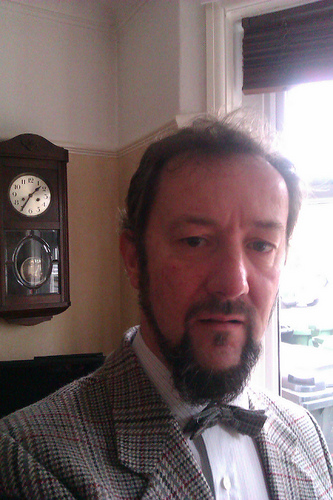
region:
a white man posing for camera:
[0, 105, 332, 497]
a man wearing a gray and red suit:
[0, 106, 330, 496]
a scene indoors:
[1, 0, 331, 498]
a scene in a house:
[4, 0, 328, 495]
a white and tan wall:
[0, 1, 197, 365]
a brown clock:
[0, 121, 84, 348]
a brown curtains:
[235, 0, 331, 106]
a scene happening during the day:
[3, 0, 318, 499]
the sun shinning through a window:
[221, 11, 332, 407]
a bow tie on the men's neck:
[173, 387, 280, 454]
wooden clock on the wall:
[0, 122, 79, 328]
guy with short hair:
[10, 111, 332, 493]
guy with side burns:
[1, 55, 332, 498]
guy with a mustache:
[5, 91, 328, 498]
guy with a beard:
[0, 99, 332, 495]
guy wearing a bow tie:
[0, 115, 329, 498]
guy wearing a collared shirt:
[1, 131, 332, 499]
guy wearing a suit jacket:
[1, 113, 331, 497]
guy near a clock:
[0, 103, 329, 498]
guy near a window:
[0, 62, 330, 496]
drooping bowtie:
[181, 401, 269, 443]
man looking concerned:
[103, 102, 308, 414]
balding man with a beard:
[109, 104, 305, 414]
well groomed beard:
[132, 257, 276, 415]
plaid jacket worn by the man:
[0, 314, 331, 499]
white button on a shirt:
[218, 475, 232, 492]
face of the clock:
[8, 169, 51, 217]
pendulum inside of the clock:
[11, 233, 51, 296]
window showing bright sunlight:
[267, 53, 332, 481]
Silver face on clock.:
[8, 180, 68, 229]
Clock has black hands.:
[14, 174, 50, 219]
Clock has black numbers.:
[14, 175, 67, 223]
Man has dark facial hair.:
[147, 287, 275, 363]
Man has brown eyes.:
[181, 227, 279, 254]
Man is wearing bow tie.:
[183, 397, 252, 433]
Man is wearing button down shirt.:
[204, 439, 255, 487]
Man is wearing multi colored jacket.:
[62, 394, 161, 473]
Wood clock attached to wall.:
[15, 130, 75, 327]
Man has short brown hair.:
[142, 111, 316, 172]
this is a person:
[0, 107, 332, 497]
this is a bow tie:
[180, 406, 273, 437]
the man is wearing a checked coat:
[0, 322, 331, 497]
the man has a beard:
[170, 302, 266, 402]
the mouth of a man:
[197, 299, 249, 336]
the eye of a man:
[174, 225, 215, 264]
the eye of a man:
[244, 236, 281, 260]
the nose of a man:
[193, 255, 255, 304]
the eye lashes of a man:
[171, 211, 219, 227]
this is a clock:
[5, 174, 53, 218]